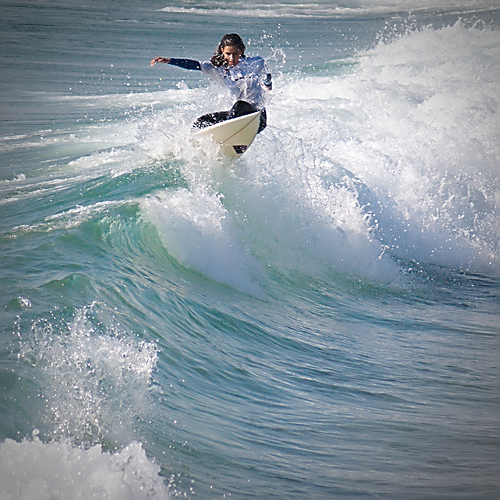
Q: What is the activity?
A: Surfboarding.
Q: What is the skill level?
A: Expert.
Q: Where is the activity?
A: At the beach.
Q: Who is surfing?
A: A young women.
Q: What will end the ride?
A: The shore.